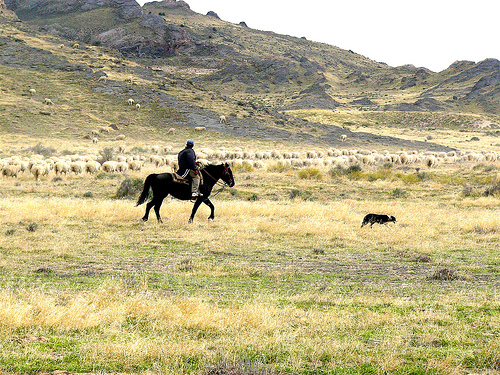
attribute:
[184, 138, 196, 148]
hat — blue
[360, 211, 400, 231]
dog — white, black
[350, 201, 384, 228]
dog — black, white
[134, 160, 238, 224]
horse — black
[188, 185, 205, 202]
shoes — white 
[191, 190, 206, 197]
shoes — white 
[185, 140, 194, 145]
hat — blue 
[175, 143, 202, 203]
man — white